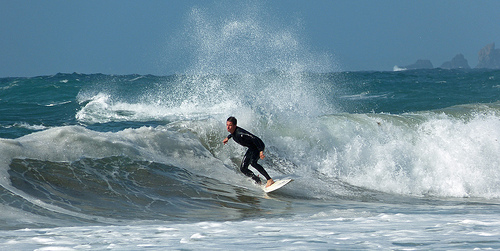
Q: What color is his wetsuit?
A: Black.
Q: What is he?
A: A surfer.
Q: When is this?
A: During the day.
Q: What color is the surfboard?
A: White.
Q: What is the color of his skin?
A: Tan.